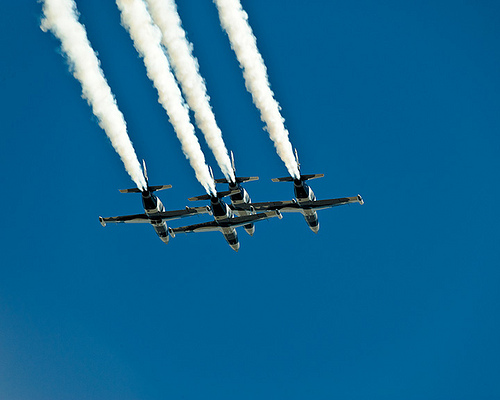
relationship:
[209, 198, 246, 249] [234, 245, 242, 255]
jet has nose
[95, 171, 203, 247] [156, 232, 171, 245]
airplanes has nose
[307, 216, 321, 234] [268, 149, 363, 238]
nose of airplanes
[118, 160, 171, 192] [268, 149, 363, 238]
tail of airplanes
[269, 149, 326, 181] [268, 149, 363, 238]
tail of airplanes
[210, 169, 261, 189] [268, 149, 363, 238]
tail of airplanes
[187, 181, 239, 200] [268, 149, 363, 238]
tail of airplanes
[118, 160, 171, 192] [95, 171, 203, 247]
tail of airplanes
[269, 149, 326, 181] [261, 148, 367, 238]
tail of jet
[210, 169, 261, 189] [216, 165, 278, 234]
tail of jet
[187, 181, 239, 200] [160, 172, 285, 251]
tail of airplane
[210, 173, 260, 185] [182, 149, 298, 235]
jet tail of jet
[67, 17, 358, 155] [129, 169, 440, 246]
tail of jet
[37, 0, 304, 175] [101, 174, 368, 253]
smoke coming from jets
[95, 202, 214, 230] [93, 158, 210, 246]
wings on plane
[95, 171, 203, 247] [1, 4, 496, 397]
airplanes flying in sky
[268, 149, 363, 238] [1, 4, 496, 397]
airplanes flying in sky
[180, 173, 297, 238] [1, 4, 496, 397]
airplane flying in sky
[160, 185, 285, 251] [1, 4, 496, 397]
airplane flying in sky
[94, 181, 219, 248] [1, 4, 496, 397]
airplane flying in sky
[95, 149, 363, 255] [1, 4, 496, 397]
airplanes flying in sky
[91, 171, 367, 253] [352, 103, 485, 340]
airplanes flying in sky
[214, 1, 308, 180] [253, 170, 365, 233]
white smoke of jet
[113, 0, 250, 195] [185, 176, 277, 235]
white smoke of jet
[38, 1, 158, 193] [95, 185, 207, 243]
white smoke of jet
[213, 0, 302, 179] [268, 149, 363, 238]
contrail coming out of airplanes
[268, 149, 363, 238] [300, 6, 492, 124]
airplanes flying in sky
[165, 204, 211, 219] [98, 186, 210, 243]
wing on airplane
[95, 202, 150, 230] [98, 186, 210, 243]
wings on airplane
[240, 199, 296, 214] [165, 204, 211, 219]
wing on wing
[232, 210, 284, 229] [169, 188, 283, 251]
wing on airplane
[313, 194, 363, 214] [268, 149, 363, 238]
wing on airplanes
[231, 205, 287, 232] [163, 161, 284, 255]
wing on airplane